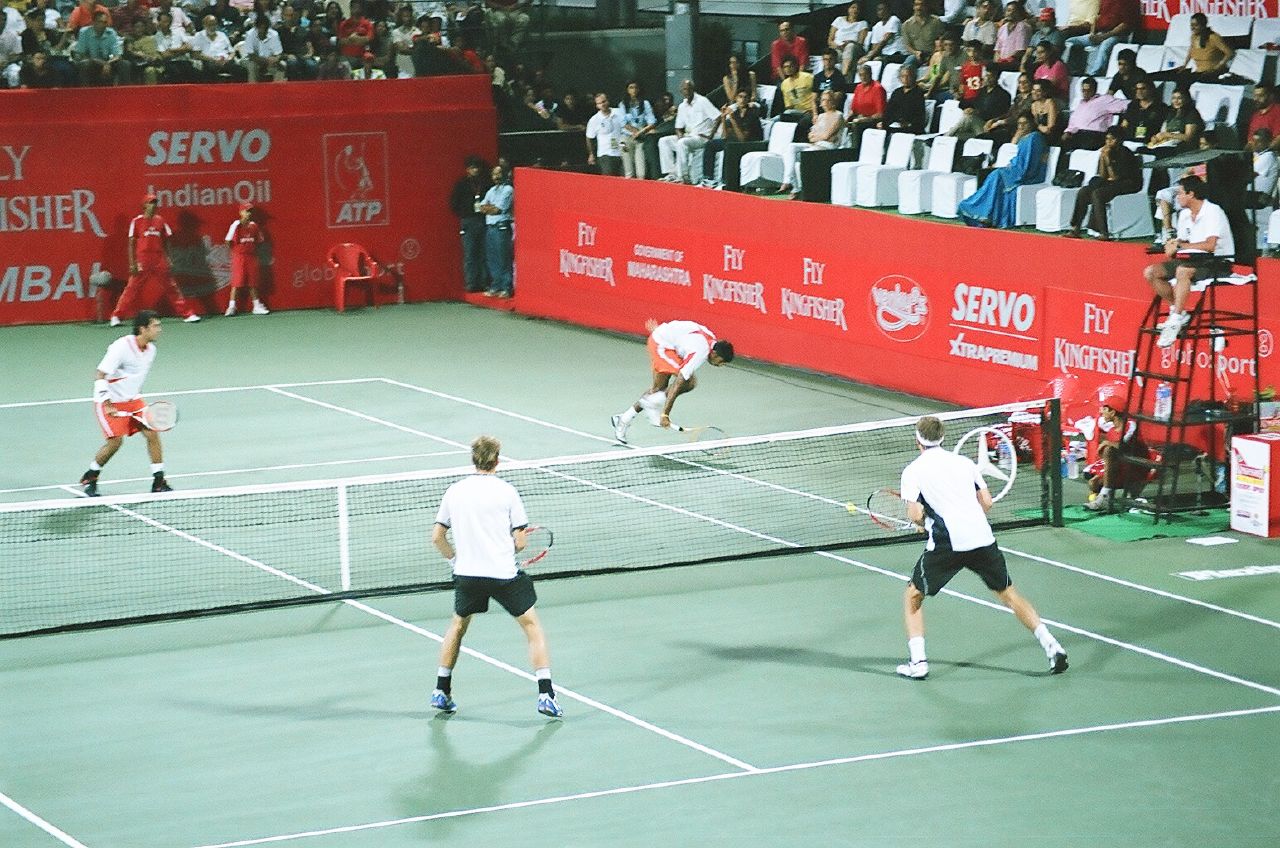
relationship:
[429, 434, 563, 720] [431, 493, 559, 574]
man in top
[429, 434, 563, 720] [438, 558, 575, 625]
man in short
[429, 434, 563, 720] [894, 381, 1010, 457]
man in headband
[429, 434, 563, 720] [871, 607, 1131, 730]
man in shoes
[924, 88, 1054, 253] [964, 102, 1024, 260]
woman in dress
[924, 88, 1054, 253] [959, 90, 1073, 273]
woman on chair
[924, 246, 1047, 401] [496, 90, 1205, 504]
letters on sign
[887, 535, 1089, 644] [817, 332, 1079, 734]
shorts on man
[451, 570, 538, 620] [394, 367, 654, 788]
short on man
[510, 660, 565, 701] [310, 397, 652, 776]
socks on man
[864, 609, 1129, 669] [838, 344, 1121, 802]
socks on man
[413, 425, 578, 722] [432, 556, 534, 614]
man wearing shorts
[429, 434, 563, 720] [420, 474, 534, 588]
man wearing shirt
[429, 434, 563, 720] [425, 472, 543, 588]
man carrying racket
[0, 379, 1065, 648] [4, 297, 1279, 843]
net on tennis court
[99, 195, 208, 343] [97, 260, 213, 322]
man has legs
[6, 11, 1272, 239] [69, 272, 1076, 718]
people watching men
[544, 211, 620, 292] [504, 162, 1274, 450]
logo on banner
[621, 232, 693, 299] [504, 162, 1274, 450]
logo on banner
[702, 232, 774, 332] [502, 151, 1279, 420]
logo on banner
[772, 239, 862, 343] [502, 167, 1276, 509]
logo on banner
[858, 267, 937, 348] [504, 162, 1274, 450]
logo on banner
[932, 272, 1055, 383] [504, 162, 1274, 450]
logo on banner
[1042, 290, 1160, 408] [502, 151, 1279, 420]
logo on banner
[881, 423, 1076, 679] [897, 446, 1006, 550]
man wearing shirt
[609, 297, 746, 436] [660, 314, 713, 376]
man wearing shirt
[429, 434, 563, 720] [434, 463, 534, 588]
man wearing shirt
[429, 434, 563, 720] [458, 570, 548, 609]
man wearing shorts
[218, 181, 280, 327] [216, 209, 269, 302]
ball boy wearing clothing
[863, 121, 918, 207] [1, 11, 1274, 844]
chair in stadium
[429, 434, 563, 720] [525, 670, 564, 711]
man wearing shoe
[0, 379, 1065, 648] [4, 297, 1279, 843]
net of tennis court